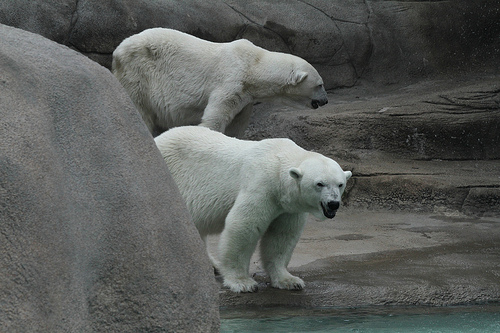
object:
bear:
[152, 123, 355, 296]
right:
[406, 222, 500, 333]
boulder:
[1, 21, 224, 332]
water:
[219, 301, 499, 333]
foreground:
[0, 213, 500, 332]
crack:
[314, 4, 378, 57]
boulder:
[0, 1, 500, 92]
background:
[0, 0, 500, 97]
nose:
[327, 199, 341, 210]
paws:
[222, 272, 260, 295]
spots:
[397, 128, 444, 162]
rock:
[245, 75, 499, 161]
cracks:
[225, 1, 293, 40]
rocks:
[204, 205, 500, 312]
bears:
[109, 25, 332, 134]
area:
[0, 0, 500, 332]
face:
[300, 165, 348, 221]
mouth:
[318, 201, 340, 220]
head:
[280, 150, 354, 221]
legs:
[215, 186, 287, 295]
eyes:
[314, 180, 327, 190]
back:
[149, 26, 238, 55]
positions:
[223, 118, 354, 293]